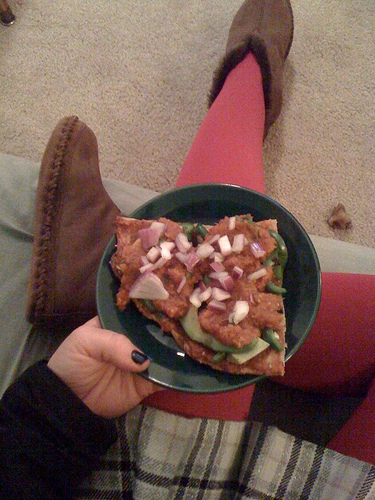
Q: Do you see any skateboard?
A: No, there are no skateboards.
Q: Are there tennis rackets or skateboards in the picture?
A: No, there are no skateboards or tennis rackets.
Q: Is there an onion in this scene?
A: Yes, there are onions.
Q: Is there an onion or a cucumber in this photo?
A: Yes, there are onions.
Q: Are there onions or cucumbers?
A: Yes, there are onions.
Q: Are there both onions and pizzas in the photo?
A: Yes, there are both onions and a pizza.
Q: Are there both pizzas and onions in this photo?
A: Yes, there are both onions and a pizza.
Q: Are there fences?
A: No, there are no fences.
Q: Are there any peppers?
A: Yes, there are peppers.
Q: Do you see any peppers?
A: Yes, there are peppers.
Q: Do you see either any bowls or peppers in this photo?
A: Yes, there are peppers.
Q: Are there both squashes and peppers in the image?
A: No, there are peppers but no squashes.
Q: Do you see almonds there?
A: No, there are no almonds.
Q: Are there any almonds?
A: No, there are no almonds.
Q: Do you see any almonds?
A: No, there are no almonds.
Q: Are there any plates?
A: Yes, there is a plate.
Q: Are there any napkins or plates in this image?
A: Yes, there is a plate.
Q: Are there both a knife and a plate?
A: No, there is a plate but no knives.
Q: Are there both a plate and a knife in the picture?
A: No, there is a plate but no knives.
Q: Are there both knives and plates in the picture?
A: No, there is a plate but no knives.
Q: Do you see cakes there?
A: No, there are no cakes.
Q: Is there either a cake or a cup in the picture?
A: No, there are no cakes or cups.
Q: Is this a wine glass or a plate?
A: This is a plate.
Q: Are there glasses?
A: No, there are no glasses.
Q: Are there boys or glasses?
A: No, there are no glasses or boys.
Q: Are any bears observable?
A: No, there are no bears.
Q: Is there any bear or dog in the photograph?
A: No, there are no bears or dogs.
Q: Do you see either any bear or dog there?
A: No, there are no bears or dogs.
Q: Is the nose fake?
A: Yes, the nose is fake.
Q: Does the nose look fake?
A: Yes, the nose is fake.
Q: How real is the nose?
A: The nose is fake.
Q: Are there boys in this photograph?
A: No, there are no boys.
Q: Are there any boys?
A: No, there are no boys.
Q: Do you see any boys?
A: No, there are no boys.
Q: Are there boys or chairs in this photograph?
A: No, there are no boys or chairs.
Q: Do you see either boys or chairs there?
A: No, there are no boys or chairs.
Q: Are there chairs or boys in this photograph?
A: No, there are no boys or chairs.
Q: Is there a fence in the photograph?
A: No, there are no fences.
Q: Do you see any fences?
A: No, there are no fences.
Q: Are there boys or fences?
A: No, there are no fences or boys.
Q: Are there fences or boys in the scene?
A: No, there are no fences or boys.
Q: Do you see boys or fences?
A: No, there are no fences or boys.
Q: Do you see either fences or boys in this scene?
A: No, there are no fences or boys.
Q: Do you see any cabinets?
A: No, there are no cabinets.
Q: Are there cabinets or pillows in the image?
A: No, there are no cabinets or pillows.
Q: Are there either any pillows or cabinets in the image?
A: No, there are no cabinets or pillows.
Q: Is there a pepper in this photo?
A: Yes, there are peppers.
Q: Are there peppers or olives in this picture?
A: Yes, there are peppers.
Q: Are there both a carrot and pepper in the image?
A: No, there are peppers but no carrots.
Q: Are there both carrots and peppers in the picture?
A: No, there are peppers but no carrots.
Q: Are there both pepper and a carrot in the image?
A: No, there are peppers but no carrots.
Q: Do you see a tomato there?
A: No, there are no tomatoes.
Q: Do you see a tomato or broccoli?
A: No, there are no tomatoes or broccoli.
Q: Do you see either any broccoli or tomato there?
A: No, there are no tomatoes or broccoli.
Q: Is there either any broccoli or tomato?
A: No, there are no tomatoes or broccoli.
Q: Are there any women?
A: Yes, there is a woman.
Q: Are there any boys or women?
A: Yes, there is a woman.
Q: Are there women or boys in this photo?
A: Yes, there is a woman.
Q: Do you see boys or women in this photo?
A: Yes, there is a woman.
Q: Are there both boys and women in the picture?
A: No, there is a woman but no boys.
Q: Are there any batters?
A: No, there are no batters.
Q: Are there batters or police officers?
A: No, there are no batters or police officers.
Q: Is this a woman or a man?
A: This is a woman.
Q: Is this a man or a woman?
A: This is a woman.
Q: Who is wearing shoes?
A: The woman is wearing shoes.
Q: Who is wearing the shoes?
A: The woman is wearing shoes.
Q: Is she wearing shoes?
A: Yes, the woman is wearing shoes.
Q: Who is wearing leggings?
A: The woman is wearing leggings.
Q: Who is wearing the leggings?
A: The woman is wearing leggings.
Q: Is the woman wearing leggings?
A: Yes, the woman is wearing leggings.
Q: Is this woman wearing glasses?
A: No, the woman is wearing leggings.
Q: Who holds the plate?
A: The woman holds the plate.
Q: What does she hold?
A: The woman holds the plate.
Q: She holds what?
A: The woman holds the plate.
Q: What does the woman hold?
A: The woman holds the plate.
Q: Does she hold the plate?
A: Yes, the woman holds the plate.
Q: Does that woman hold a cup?
A: No, the woman holds the plate.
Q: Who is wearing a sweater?
A: The woman is wearing a sweater.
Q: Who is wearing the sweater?
A: The woman is wearing a sweater.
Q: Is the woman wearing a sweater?
A: Yes, the woman is wearing a sweater.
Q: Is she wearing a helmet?
A: No, the woman is wearing a sweater.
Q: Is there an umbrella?
A: No, there are no umbrellas.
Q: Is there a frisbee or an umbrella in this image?
A: No, there are no umbrellas or frisbees.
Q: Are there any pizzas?
A: Yes, there is a pizza.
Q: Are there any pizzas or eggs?
A: Yes, there is a pizza.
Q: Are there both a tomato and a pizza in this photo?
A: No, there is a pizza but no tomatoes.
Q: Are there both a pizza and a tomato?
A: No, there is a pizza but no tomatoes.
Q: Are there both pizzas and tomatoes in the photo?
A: No, there is a pizza but no tomatoes.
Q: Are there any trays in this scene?
A: No, there are no trays.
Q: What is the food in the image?
A: The food is a pizza.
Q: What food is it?
A: The food is a pizza.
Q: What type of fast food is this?
A: This is a pizza.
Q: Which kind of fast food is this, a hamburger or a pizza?
A: This is a pizza.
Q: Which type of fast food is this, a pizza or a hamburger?
A: This is a pizza.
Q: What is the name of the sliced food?
A: The food is a pizza.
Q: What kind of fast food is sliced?
A: The fast food is a pizza.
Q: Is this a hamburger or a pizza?
A: This is a pizza.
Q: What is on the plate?
A: The pizza is on the plate.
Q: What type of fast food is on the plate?
A: The food is a pizza.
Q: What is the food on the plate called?
A: The food is a pizza.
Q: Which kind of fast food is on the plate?
A: The food is a pizza.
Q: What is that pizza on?
A: The pizza is on the plate.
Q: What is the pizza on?
A: The pizza is on the plate.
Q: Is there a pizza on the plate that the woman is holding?
A: Yes, there is a pizza on the plate.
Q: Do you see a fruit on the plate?
A: No, there is a pizza on the plate.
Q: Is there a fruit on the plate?
A: No, there is a pizza on the plate.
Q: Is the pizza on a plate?
A: Yes, the pizza is on a plate.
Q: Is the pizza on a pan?
A: No, the pizza is on a plate.